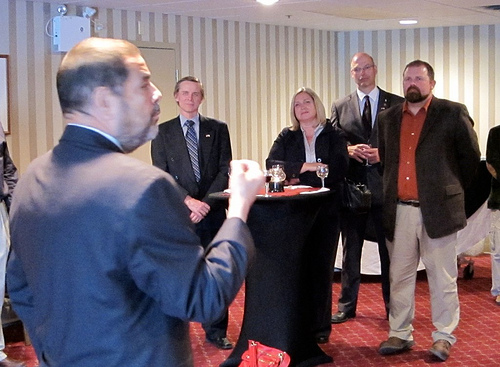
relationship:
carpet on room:
[2, 249, 497, 364] [0, 0, 500, 365]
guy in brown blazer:
[377, 58, 484, 363] [370, 91, 482, 248]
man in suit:
[150, 76, 233, 349] [156, 117, 230, 209]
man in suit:
[330, 52, 406, 324] [330, 92, 392, 317]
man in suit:
[7, 37, 264, 364] [10, 132, 258, 364]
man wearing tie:
[330, 52, 406, 324] [363, 92, 374, 129]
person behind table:
[265, 87, 352, 343] [214, 163, 344, 351]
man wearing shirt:
[362, 50, 476, 260] [335, 119, 493, 219]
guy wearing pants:
[377, 59, 481, 361] [388, 197, 461, 342]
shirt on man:
[396, 95, 434, 202] [347, 50, 480, 359]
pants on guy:
[377, 197, 464, 344] [377, 59, 481, 361]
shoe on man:
[422, 326, 457, 363] [357, 49, 484, 359]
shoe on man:
[368, 321, 414, 354] [357, 49, 484, 359]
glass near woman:
[315, 161, 330, 188] [264, 88, 353, 325]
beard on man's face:
[406, 86, 429, 103] [400, 68, 436, 104]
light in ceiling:
[399, 17, 419, 29] [4, 0, 482, 56]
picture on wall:
[0, 52, 10, 134] [2, 1, 340, 177]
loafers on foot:
[374, 323, 459, 365] [375, 324, 412, 356]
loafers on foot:
[374, 323, 459, 365] [421, 325, 450, 365]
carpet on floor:
[2, 249, 497, 364] [342, 297, 460, 362]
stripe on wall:
[175, 14, 212, 82] [187, 26, 483, 145]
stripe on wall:
[196, 18, 236, 92] [187, 26, 483, 145]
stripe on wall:
[277, 32, 306, 86] [187, 26, 483, 145]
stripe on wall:
[453, 29, 473, 98] [187, 26, 483, 145]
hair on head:
[56, 37, 141, 114] [55, 36, 161, 152]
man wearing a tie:
[330, 52, 406, 324] [359, 94, 372, 136]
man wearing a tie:
[150, 74, 233, 347] [183, 118, 203, 181]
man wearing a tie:
[330, 52, 406, 324] [360, 93, 373, 141]